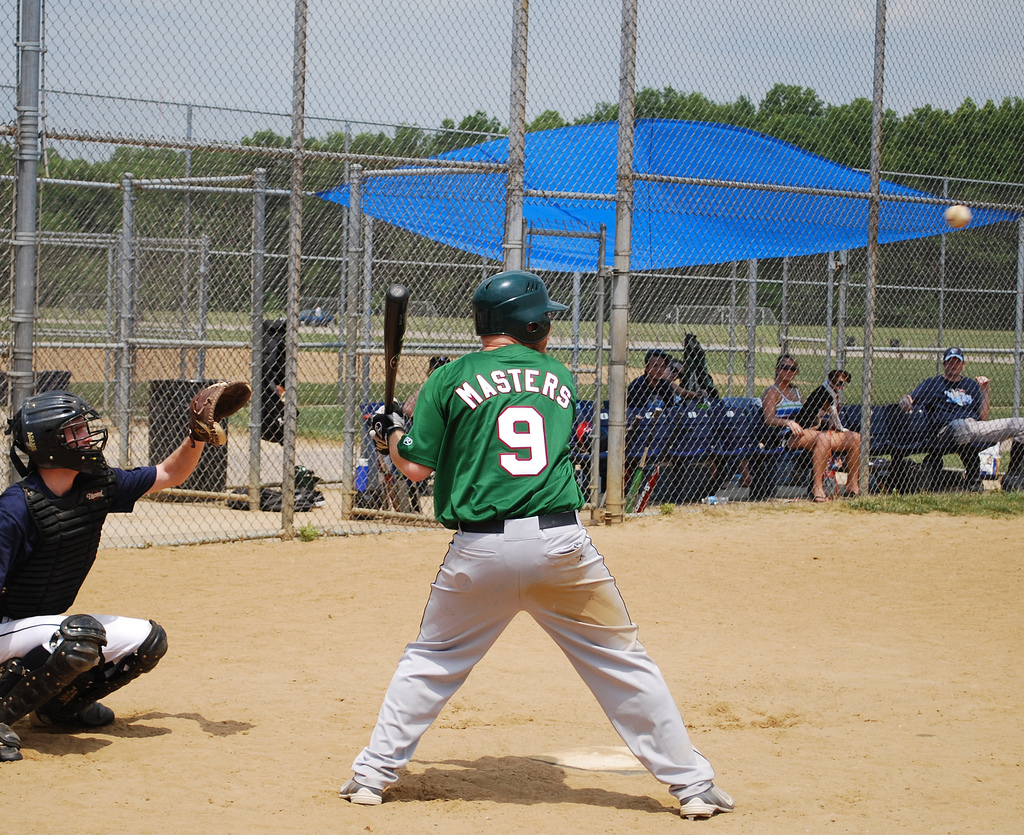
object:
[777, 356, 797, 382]
face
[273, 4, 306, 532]
pole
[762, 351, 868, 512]
person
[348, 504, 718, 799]
pants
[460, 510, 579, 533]
belt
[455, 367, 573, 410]
name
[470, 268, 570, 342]
helmet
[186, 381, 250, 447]
glove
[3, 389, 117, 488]
helmet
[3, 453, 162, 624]
shirt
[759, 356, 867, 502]
people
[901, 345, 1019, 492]
people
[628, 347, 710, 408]
people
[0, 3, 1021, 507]
fence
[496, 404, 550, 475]
number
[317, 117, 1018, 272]
tarp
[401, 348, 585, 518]
shirt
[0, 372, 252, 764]
catcher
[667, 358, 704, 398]
person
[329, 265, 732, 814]
batter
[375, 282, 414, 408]
bat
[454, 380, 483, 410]
letter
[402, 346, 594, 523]
jersey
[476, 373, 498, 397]
letter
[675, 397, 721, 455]
chairs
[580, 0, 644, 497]
posts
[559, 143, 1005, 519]
fencing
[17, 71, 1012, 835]
game